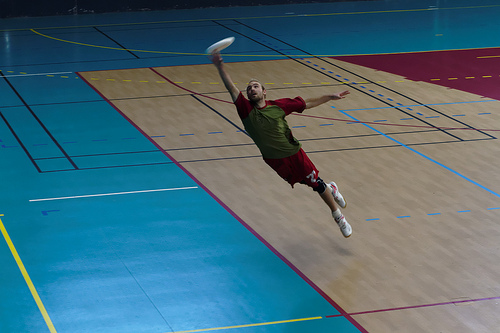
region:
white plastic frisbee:
[193, 23, 239, 64]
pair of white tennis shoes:
[323, 180, 365, 247]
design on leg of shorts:
[304, 167, 320, 184]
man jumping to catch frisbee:
[190, 24, 400, 256]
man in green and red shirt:
[219, 60, 329, 154]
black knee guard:
[297, 167, 334, 197]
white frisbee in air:
[192, 24, 243, 64]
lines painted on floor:
[340, 67, 498, 178]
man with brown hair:
[235, 71, 275, 113]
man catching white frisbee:
[199, 20, 349, 152]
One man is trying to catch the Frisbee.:
[183, 33, 366, 219]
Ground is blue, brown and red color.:
[175, 208, 375, 291]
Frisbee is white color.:
[187, 20, 246, 73]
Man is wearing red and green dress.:
[236, 90, 318, 190]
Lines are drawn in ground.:
[36, 48, 430, 308]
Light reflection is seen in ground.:
[3, 25, 28, 63]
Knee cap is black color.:
[302, 169, 330, 196]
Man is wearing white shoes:
[331, 173, 383, 265]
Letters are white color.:
[300, 166, 321, 187]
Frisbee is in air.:
[205, 38, 246, 59]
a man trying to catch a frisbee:
[203, 27, 361, 241]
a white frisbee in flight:
[204, 32, 240, 54]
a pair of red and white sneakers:
[324, 175, 355, 239]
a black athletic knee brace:
[303, 172, 331, 194]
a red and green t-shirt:
[231, 90, 311, 161]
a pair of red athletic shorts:
[257, 137, 329, 187]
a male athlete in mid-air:
[207, 49, 357, 244]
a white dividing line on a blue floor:
[26, 177, 203, 207]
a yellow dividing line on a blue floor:
[0, 209, 60, 331]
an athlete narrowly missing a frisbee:
[199, 31, 356, 248]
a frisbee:
[203, 42, 260, 57]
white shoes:
[328, 208, 356, 238]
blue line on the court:
[425, 148, 473, 192]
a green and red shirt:
[231, 101, 300, 161]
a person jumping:
[178, 26, 388, 238]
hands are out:
[305, 84, 369, 107]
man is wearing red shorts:
[264, 158, 319, 179]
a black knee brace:
[311, 176, 329, 195]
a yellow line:
[13, 254, 64, 324]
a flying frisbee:
[203, 38, 243, 58]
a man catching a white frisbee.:
[176, 8, 368, 246]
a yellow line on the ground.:
[6, 200, 63, 331]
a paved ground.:
[78, 36, 495, 331]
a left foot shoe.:
[332, 203, 357, 248]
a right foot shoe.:
[313, 151, 359, 198]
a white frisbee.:
[199, 23, 241, 63]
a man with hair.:
[243, 80, 274, 122]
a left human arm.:
[280, 68, 360, 138]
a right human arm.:
[209, 57, 245, 120]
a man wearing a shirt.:
[229, 91, 306, 176]